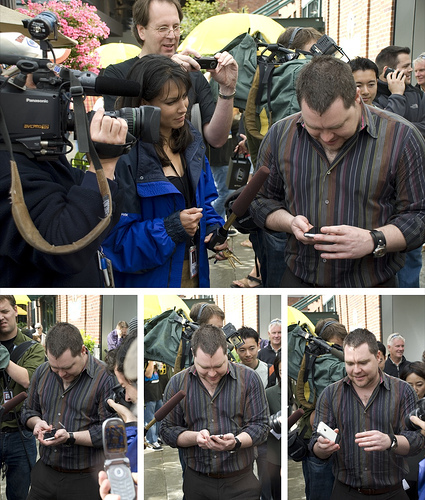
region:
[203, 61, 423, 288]
a man looking at his phone.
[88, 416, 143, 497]
an outdated flip phone.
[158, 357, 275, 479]
a gray and stripe shirt.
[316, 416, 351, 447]
a smart phone.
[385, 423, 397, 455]
an outdated watch.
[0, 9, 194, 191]
a huge old camera.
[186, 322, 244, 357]
a receding hairline.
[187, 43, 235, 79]
a person holding a camera.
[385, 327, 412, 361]
a man with gray hair.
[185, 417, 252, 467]
a phone in hands.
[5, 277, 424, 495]
A step by step photo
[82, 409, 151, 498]
An opened flip phone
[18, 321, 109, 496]
He is looking at his phone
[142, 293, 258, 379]
Camera man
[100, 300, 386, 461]
Crowd in the back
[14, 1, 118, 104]
Pink petals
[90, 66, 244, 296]
A woman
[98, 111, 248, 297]
Woman wearing a blue jacket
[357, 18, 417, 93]
Talking on the phone in public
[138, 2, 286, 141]
Light green leaves in back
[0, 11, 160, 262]
photographer holds TV camera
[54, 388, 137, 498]
person takes picture with flip top cell phone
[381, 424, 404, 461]
mens wrist watch with black band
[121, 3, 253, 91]
man takes photo with black camera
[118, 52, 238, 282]
reporter in bright blue jacket hold a microphone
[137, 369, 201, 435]
a long brown covered microphone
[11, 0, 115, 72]
tree with pink flowers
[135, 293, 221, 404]
cameraman wears green jacket and head phones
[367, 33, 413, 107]
man talks on cell phone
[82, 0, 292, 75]
yellow umbrellas set up beyond the gathering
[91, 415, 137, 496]
An open cellphone.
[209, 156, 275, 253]
A microphone.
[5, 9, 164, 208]
A black news camera.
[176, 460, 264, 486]
A brown belt on the man with brown pants.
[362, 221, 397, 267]
A black wrist watch.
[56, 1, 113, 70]
Pink flowers on a tree.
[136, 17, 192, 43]
Eyeglasses on a man.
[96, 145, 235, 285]
A blue colored coat on the woman.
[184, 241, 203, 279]
An identification badge.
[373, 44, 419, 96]
A man holding a cellphone to his ear.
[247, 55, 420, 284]
man in striped shirt looking down at an iPhone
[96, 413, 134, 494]
cellphone being held in right foreground of man in striped shirt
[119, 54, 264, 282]
a woman in a blue jacket holding a microphone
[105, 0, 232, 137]
man in glasses taking photograph of man in striped shirt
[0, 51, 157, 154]
hand held camera in left foreground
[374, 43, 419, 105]
man talking on cellphone looking to the right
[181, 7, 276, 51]
top of yellow umbrella to the right of man wearing glasses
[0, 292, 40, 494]
part of cameraman facing ahead on far left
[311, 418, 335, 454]
man in striped shirt holding iPhone with logo showing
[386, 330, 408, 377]
man with gray hair in background looking towards right